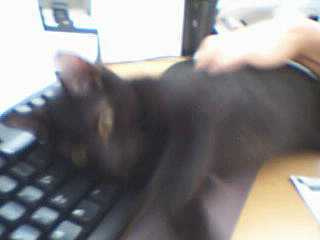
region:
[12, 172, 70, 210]
this is a keyboard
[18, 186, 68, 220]
the keyboard has buttons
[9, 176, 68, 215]
the buttons are many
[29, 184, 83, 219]
the buttons are black in color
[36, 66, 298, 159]
this is a cat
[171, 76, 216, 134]
the fur is black in color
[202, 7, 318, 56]
this is a hand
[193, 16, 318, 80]
the hand is on the cat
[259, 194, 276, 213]
this is a table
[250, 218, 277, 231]
the table is wooden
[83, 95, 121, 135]
blurry eye of a black cat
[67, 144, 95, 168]
blurry eye of a black cat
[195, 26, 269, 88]
blurry hand petting a cat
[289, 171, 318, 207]
a piece of paper on the desk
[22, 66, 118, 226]
a black cat laying on a keyboard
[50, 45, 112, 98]
ear on a black cat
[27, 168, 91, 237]
black keys on a keyboard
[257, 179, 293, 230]
a light wooden desk top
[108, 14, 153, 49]
a white wall in the background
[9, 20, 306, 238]
a black cat being pet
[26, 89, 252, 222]
This is a cat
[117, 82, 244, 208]
The cat is black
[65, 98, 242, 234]
The cat is blurry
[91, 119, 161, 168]
The cat has green eyes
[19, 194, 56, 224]
This is a keyboard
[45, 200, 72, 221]
The keyboard is black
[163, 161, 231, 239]
This is an arm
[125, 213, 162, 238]
This is a paw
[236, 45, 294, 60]
This is a hand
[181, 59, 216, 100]
These are many fingers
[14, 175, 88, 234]
this is a keyboard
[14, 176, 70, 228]
these are some buttons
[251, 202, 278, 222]
this is the table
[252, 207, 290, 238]
the table is wooden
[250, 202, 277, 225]
the table is brown in color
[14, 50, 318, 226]
this is a cat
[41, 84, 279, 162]
the cat is big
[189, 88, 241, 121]
the fur is black in color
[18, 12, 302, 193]
blurry picture of a cat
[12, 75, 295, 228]
cat laying on keyboard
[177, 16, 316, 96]
person with hand on cat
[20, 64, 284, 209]
cat in motion is the cause of the blur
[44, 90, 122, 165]
cat has yellow or green eyes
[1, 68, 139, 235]
black keyboard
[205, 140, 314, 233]
wooden desktop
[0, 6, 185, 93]
white background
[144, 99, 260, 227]
cat stretching its arms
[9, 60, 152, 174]
cat with head on keyboard